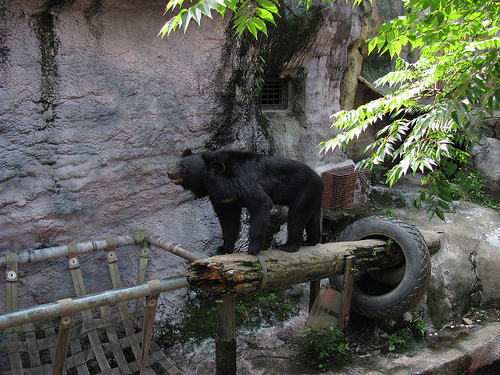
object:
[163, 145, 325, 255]
bear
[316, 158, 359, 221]
basket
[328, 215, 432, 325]
tire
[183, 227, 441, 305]
tree trunk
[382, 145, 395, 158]
tree leaf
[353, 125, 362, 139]
tree leaf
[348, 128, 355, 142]
tree leaf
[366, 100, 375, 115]
tree leaf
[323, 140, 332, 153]
tree leaf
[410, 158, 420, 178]
leaf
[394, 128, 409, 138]
leaf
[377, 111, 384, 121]
leaf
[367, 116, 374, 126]
leaf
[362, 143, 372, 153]
leaf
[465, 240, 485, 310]
crack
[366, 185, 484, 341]
rock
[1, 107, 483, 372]
ground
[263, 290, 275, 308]
plant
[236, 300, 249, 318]
plant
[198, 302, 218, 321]
plant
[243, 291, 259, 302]
plant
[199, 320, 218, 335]
plant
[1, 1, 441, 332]
wall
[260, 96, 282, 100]
bar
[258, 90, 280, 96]
bar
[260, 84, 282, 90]
bar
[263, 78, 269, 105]
bar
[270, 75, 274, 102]
bar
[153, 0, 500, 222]
tree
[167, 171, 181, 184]
tongue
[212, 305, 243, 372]
post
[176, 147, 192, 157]
left ear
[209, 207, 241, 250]
left leg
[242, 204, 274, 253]
right leg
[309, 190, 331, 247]
left leg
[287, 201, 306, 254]
right leg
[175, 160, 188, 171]
eye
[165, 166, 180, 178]
nose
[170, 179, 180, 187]
mouth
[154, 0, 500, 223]
tree branches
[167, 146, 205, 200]
head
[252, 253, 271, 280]
leaves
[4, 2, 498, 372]
enclosure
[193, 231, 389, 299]
log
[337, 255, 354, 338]
post